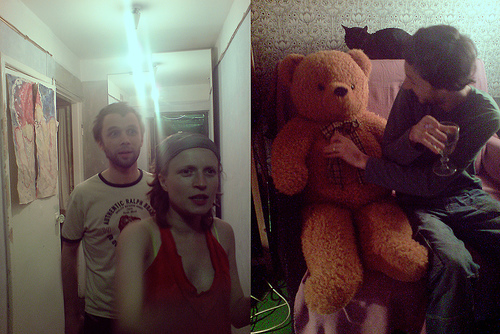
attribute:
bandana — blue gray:
[158, 131, 222, 180]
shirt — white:
[58, 170, 160, 319]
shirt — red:
[124, 206, 243, 326]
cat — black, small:
[338, 22, 411, 58]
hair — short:
[93, 98, 137, 146]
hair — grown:
[150, 134, 227, 232]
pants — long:
[409, 180, 482, 310]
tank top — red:
[146, 217, 246, 328]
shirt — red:
[136, 215, 239, 332]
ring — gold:
[330, 132, 340, 144]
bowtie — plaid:
[323, 120, 370, 188]